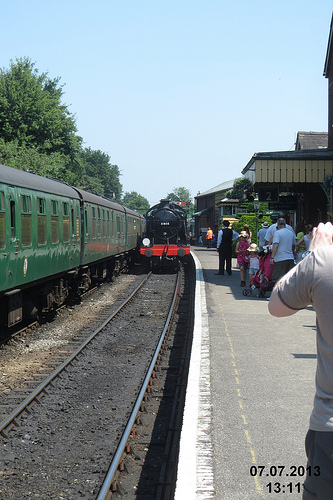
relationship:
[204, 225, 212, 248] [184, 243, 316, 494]
man on platform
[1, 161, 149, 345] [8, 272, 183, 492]
train on tracks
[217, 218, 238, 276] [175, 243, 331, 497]
person on platform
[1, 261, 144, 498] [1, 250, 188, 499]
gravel by track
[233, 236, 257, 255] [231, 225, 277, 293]
outfit on girl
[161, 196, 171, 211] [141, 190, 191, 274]
smokestack on locomotive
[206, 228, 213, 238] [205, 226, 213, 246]
vest on man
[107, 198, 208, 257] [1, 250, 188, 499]
train on track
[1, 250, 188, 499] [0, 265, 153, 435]
track has rail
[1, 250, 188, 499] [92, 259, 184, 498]
track has rail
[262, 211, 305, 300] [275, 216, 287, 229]
man has head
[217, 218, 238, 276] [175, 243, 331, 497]
person standing at platform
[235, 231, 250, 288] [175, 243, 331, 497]
girl standing at platform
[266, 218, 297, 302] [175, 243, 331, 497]
man standing at platform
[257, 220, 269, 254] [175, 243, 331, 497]
person standing at platform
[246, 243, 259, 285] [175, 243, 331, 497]
person standing at platform